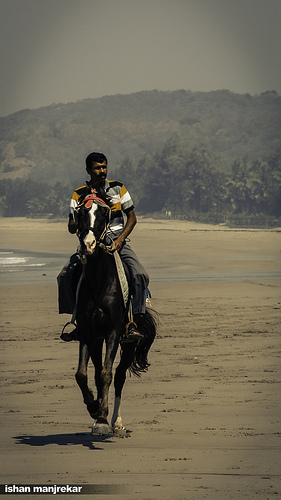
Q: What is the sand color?
A: Tan.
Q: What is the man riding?
A: Horse.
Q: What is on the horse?
A: A man.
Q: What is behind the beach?
A: A mountain.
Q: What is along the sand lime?
A: Trees.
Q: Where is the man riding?
A: The beach.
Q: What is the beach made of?
A: Sand.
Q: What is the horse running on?
A: Sand.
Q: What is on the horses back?
A: Saddle.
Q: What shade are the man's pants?
A: Grey.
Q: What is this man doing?
A: Riding the horse.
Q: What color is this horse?
A: Black.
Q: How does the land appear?
A: Sandy.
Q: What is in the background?
A: Trees.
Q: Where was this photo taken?
A: On a beach.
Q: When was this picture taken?
A: In the daytime.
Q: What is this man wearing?
A: Shirt and jeans.